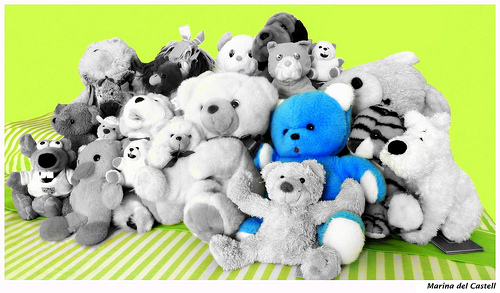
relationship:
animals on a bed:
[52, 32, 448, 254] [5, 262, 113, 274]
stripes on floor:
[9, 219, 493, 287] [6, 193, 490, 280]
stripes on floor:
[7, 123, 495, 281] [13, 167, 499, 291]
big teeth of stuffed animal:
[38, 170, 63, 188] [13, 129, 78, 226]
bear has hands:
[210, 155, 365, 280] [227, 175, 366, 210]